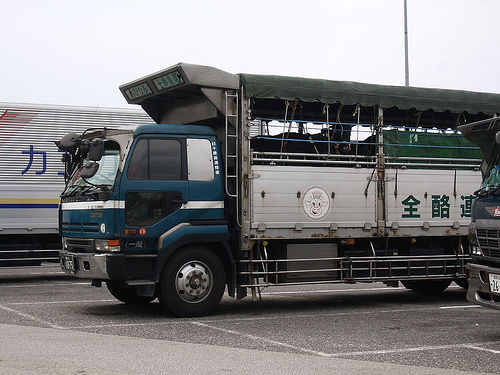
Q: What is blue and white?
A: Truck.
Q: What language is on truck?
A: Foreign.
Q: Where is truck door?
A: Side of vehicle.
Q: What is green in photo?
A: Roof on truck.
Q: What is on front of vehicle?
A: Passenger cab.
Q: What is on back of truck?
A: Trailer.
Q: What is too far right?
A: Front of truck grille.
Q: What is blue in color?
A: The truck.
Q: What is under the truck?
A: Tire.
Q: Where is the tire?
A: On the truck.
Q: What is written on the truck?
A: Symbols.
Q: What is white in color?
A: The lines.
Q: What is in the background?
A: The sky.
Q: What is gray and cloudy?
A: The sky.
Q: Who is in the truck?
A: No one.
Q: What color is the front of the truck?
A: Blue.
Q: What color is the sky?
A: Grey.